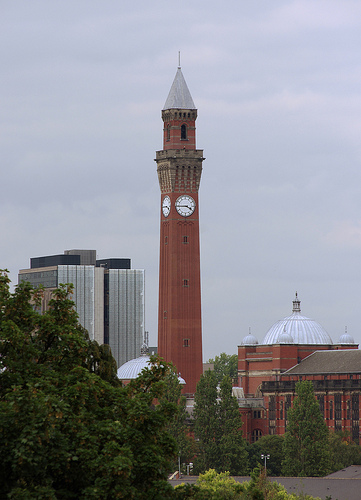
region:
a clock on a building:
[131, 177, 231, 233]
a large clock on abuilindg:
[141, 189, 180, 226]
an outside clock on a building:
[138, 188, 203, 257]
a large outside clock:
[163, 179, 186, 221]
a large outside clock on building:
[156, 184, 209, 239]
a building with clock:
[158, 191, 192, 231]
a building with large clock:
[155, 186, 193, 237]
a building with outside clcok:
[162, 180, 201, 227]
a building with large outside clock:
[161, 184, 186, 212]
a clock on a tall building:
[155, 183, 200, 236]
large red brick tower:
[135, 69, 213, 367]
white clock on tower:
[167, 161, 195, 227]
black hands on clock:
[165, 186, 192, 227]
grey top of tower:
[165, 71, 193, 117]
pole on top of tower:
[171, 49, 185, 72]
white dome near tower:
[254, 280, 335, 341]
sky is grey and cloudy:
[265, 84, 352, 240]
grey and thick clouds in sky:
[233, 94, 350, 239]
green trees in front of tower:
[0, 233, 210, 487]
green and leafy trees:
[22, 284, 161, 479]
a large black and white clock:
[160, 196, 169, 213]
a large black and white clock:
[175, 193, 193, 214]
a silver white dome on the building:
[111, 356, 187, 379]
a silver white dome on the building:
[243, 333, 259, 346]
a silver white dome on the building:
[264, 316, 330, 345]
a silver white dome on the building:
[337, 331, 353, 344]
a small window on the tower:
[182, 233, 188, 243]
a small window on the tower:
[183, 277, 188, 286]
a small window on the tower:
[181, 336, 190, 345]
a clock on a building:
[151, 191, 206, 226]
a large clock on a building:
[145, 191, 211, 236]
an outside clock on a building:
[153, 178, 203, 231]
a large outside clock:
[167, 173, 200, 232]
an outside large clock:
[153, 183, 206, 240]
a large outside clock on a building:
[150, 183, 203, 257]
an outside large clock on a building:
[158, 189, 205, 247]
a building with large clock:
[155, 181, 211, 239]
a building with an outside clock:
[152, 181, 204, 230]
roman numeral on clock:
[183, 194, 187, 200]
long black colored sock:
[180, 195, 184, 201]